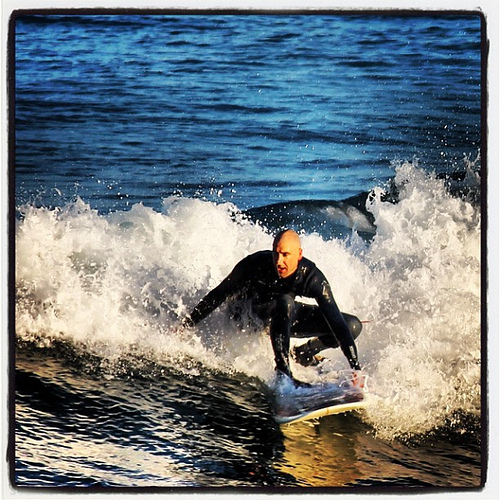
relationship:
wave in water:
[20, 138, 481, 445] [14, 12, 481, 486]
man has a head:
[183, 228, 364, 376] [271, 226, 303, 277]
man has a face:
[183, 228, 364, 376] [273, 245, 293, 276]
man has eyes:
[183, 228, 364, 376] [273, 249, 290, 259]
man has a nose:
[183, 228, 364, 376] [275, 252, 282, 266]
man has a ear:
[183, 228, 364, 376] [296, 245, 302, 257]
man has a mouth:
[183, 228, 364, 376] [276, 263, 289, 269]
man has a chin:
[183, 228, 364, 376] [274, 271, 287, 279]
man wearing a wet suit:
[183, 228, 364, 376] [183, 250, 363, 372]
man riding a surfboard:
[183, 228, 364, 376] [271, 370, 368, 428]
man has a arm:
[183, 228, 364, 376] [308, 269, 359, 369]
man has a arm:
[183, 228, 364, 376] [182, 251, 249, 328]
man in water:
[183, 228, 364, 376] [14, 12, 481, 486]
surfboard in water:
[271, 370, 368, 428] [14, 12, 481, 486]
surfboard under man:
[271, 370, 368, 428] [183, 228, 364, 376]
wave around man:
[20, 138, 481, 445] [183, 228, 364, 376]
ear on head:
[296, 245, 302, 257] [271, 226, 303, 277]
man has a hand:
[183, 228, 364, 376] [347, 369, 363, 388]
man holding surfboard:
[183, 228, 364, 376] [271, 370, 368, 428]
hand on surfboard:
[347, 369, 363, 388] [271, 370, 368, 428]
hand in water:
[347, 369, 363, 388] [14, 12, 481, 486]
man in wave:
[183, 228, 364, 376] [20, 138, 481, 445]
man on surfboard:
[183, 228, 364, 376] [271, 370, 368, 428]